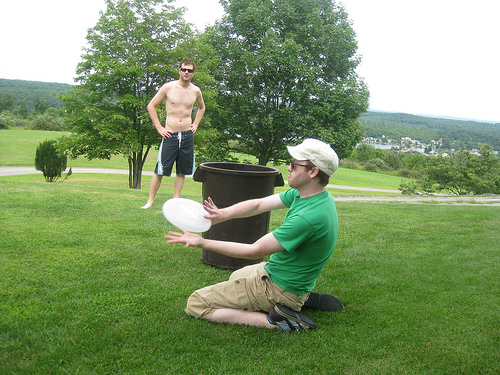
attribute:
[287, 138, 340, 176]
hat — white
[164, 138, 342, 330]
man — playing frisbee, catching frisbee, shirtless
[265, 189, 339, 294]
shirt — green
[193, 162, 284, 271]
garbage can — dark, between the men, large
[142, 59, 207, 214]
man — wearing no shirt, playing frisbee, without shirt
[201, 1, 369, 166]
tree — large, green, landscaped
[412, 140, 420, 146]
building — in distance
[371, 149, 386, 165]
tree — small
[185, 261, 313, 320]
pants — beige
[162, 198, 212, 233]
frisbee — white, in the air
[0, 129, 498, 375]
grass — green, large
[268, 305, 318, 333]
shoe — black, blue, on feet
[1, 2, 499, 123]
sky — white